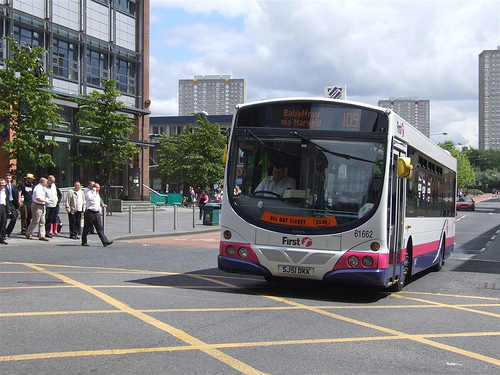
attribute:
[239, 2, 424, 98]
clouds — white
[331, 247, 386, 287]
stripes — pink, purple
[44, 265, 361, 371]
crosswalk — yellow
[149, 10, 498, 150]
sky — blue, white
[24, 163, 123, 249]
people — walking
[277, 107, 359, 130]
lcd — orange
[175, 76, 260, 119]
building — tall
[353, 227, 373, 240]
numbers — black